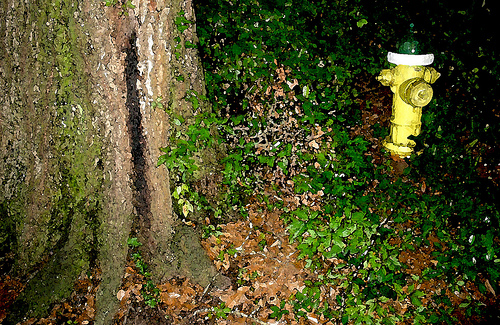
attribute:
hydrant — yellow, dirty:
[373, 21, 442, 158]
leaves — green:
[194, 0, 498, 324]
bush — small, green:
[288, 201, 373, 261]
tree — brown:
[2, 0, 272, 323]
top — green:
[386, 29, 434, 66]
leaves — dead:
[157, 280, 204, 316]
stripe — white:
[385, 51, 436, 64]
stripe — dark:
[121, 35, 150, 220]